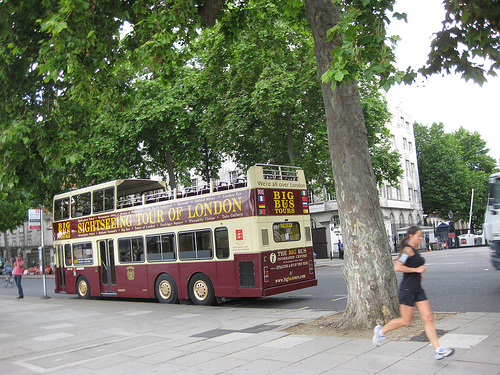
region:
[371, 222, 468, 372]
girl running down side walk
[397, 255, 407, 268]
grey arm band on arm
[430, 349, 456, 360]
white running shoes on feet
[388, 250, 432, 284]
black top on girl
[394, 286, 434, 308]
black running shorts on girl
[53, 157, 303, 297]
large bus parked on road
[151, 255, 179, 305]
small black wheel of bus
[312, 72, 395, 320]
long brown trunk of tree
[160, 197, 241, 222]
yellow writing on bus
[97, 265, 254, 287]
red color on bottom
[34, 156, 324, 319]
a London touring bus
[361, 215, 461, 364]
a woman jogging down the sidewalk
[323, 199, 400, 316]
the trunk of a tree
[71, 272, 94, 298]
the front wheel of a bus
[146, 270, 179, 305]
the rear wheel of a bus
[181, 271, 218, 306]
the rear wheel of a bus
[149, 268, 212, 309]
the rear wheels of a bus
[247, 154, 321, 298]
the back of a bus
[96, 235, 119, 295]
the loading door of a bus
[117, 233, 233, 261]
the windows of a bus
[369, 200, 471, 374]
the woman is jogging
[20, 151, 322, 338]
a tourist bus is parked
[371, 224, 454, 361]
Woman out jogging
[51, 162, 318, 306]
Sightseeing tour of London bus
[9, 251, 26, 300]
Woman in a pink shirt and blue jeans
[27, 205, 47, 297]
Red, white and blue signpost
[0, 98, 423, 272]
Buildings and urban architecture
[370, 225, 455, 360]
Woman wearing black athletic clothes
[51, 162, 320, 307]
Double decker bus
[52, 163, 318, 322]
Red and beige colored bus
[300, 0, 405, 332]
Trunk of a live tree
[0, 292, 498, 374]
Paved sidewalk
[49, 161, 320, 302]
a sightseeing bus is parked at curbside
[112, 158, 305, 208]
this sightseeing bus has an open-air upper deck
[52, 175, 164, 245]
part of the upper deck of this bus has a roof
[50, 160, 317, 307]
this sightseeing bus is maroon and white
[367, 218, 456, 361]
a jogger runs along the sidewalk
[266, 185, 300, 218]
this sightseeing bus is owned by Big Bus Tours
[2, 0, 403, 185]
many green leafy trees around the bus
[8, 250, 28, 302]
this pedestrian is wearing a pink top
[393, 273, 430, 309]
this jogger is wearing black shorts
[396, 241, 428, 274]
this jogger is wearing a black top